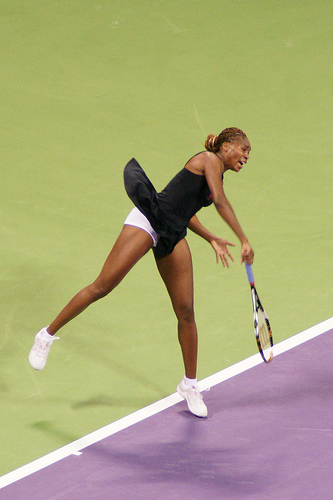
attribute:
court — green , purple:
[29, 307, 317, 498]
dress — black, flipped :
[123, 150, 220, 259]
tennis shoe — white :
[24, 322, 62, 372]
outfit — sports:
[122, 152, 228, 260]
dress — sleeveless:
[110, 133, 234, 265]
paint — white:
[48, 427, 116, 459]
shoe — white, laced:
[179, 372, 216, 416]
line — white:
[135, 237, 306, 486]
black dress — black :
[119, 155, 220, 259]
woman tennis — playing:
[18, 110, 283, 428]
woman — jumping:
[29, 125, 254, 417]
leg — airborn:
[22, 202, 153, 371]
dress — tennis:
[123, 148, 205, 253]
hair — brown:
[199, 122, 252, 155]